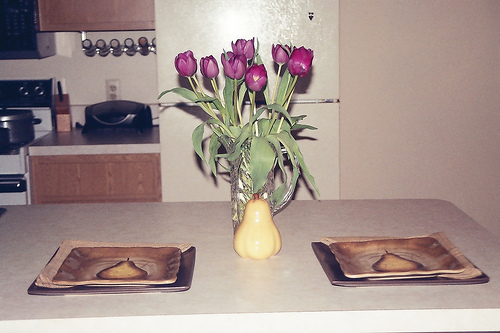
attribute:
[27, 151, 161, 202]
cabinet — wooden, handleless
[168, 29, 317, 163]
tulips — purple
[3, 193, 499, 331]
table — large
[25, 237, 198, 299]
plate — square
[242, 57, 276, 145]
flower — purple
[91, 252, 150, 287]
pear — yellow, fake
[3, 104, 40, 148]
pot — silver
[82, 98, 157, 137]
player — black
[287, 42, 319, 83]
tulip — purple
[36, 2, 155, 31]
cabinet — wooden, handleless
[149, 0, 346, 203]
refrigerator — white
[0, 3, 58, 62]
microwave — black